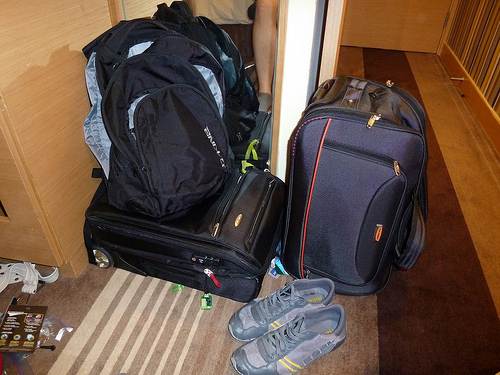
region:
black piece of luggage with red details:
[272, 75, 429, 298]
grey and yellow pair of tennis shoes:
[225, 274, 346, 373]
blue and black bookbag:
[82, 21, 232, 213]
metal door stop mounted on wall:
[448, 73, 468, 88]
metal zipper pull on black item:
[392, 160, 401, 176]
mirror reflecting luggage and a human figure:
[109, 1, 282, 174]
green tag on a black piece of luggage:
[199, 273, 214, 311]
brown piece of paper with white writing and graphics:
[0, 303, 50, 355]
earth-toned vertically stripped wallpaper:
[442, 0, 499, 118]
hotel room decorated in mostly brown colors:
[2, 1, 493, 366]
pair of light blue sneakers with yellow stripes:
[227, 278, 342, 370]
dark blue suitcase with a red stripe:
[284, 75, 429, 297]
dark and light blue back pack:
[78, 6, 258, 214]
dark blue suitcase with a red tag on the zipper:
[85, 154, 285, 306]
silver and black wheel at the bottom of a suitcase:
[88, 247, 113, 271]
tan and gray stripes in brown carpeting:
[45, 264, 227, 373]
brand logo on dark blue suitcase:
[373, 220, 384, 249]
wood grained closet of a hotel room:
[1, 1, 125, 278]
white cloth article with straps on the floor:
[0, 258, 59, 296]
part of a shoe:
[279, 353, 281, 356]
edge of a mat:
[365, 320, 390, 359]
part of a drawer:
[78, 233, 92, 249]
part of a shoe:
[298, 292, 309, 312]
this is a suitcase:
[274, 56, 454, 326]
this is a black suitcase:
[72, 155, 297, 313]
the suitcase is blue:
[278, 25, 435, 301]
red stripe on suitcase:
[296, 102, 338, 288]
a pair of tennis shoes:
[220, 265, 365, 372]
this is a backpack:
[72, 12, 242, 230]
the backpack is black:
[73, 7, 255, 218]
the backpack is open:
[59, 5, 274, 212]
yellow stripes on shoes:
[266, 340, 311, 374]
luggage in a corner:
[26, 6, 480, 374]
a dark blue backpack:
[81, 2, 266, 232]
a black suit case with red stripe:
[283, 52, 428, 313]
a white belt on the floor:
[5, 257, 67, 313]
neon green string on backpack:
[231, 131, 277, 213]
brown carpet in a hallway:
[347, 47, 499, 362]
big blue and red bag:
[281, 73, 429, 296]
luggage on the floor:
[76, 0, 431, 296]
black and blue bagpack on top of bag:
[83, 14, 230, 226]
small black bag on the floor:
[84, 160, 286, 307]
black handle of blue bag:
[389, 198, 428, 273]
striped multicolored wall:
[446, 1, 499, 119]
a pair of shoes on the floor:
[215, 287, 361, 374]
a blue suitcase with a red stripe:
[299, 98, 434, 297]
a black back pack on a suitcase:
[107, 50, 227, 210]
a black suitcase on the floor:
[78, 178, 279, 307]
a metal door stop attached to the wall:
[447, 72, 469, 84]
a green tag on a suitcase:
[193, 278, 217, 314]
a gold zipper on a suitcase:
[390, 153, 404, 179]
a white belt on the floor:
[6, 253, 57, 297]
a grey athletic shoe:
[230, 302, 347, 373]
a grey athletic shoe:
[227, 279, 333, 343]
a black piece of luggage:
[282, 74, 428, 299]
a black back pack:
[86, 18, 233, 222]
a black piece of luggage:
[81, 154, 288, 304]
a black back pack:
[153, 2, 257, 142]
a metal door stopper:
[447, 74, 466, 82]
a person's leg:
[255, 0, 277, 108]